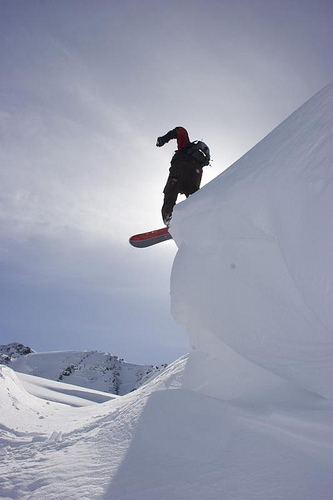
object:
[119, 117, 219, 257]
snowboarder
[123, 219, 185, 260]
snowboard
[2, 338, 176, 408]
hills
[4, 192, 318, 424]
distance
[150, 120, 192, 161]
arm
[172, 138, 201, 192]
backpack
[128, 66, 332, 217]
top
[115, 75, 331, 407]
drift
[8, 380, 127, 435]
valley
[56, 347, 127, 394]
trees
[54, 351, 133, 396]
foliage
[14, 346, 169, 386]
hill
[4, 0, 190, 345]
sky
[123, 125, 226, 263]
person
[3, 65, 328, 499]
snow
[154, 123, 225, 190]
jacket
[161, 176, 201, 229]
pants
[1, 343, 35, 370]
rock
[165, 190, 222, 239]
ledge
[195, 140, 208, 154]
helmet